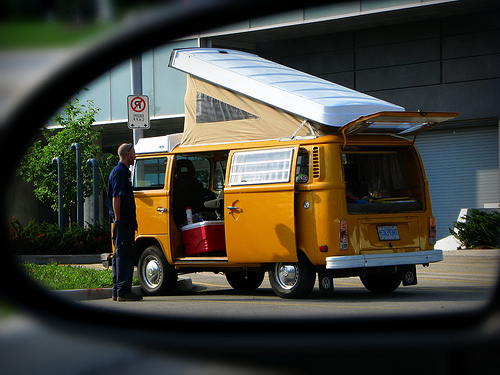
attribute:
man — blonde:
[105, 142, 142, 303]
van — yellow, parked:
[107, 46, 446, 290]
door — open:
[225, 147, 298, 267]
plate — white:
[375, 223, 401, 240]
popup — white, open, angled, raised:
[166, 47, 413, 139]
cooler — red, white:
[181, 218, 226, 251]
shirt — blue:
[105, 162, 141, 224]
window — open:
[339, 106, 453, 144]